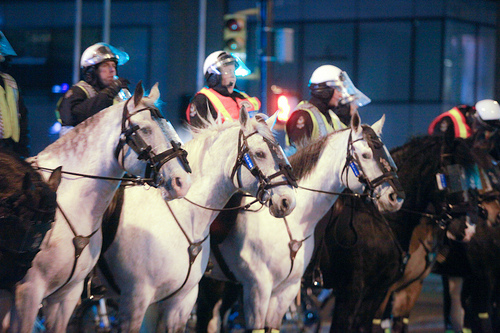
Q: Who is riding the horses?
A: Police officers.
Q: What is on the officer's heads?
A: Helmets.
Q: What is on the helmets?
A: Shield.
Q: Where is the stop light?
A: Behind the police officers.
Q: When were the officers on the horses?
A: During the evening.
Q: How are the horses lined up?
A: In a single line.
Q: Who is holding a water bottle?
A: An officer on one of the white horses.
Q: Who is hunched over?
A: A police officer.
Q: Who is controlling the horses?
A: Police officers.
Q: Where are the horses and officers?
A: In a downtown area.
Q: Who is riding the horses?
A: Police officers.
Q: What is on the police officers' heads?
A: Helmets.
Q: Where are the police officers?
A: On the horses.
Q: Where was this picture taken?
A: On a street.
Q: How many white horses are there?
A: Three.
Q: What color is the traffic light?
A: Green.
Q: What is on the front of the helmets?
A: Visors.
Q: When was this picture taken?
A: Nighttime.